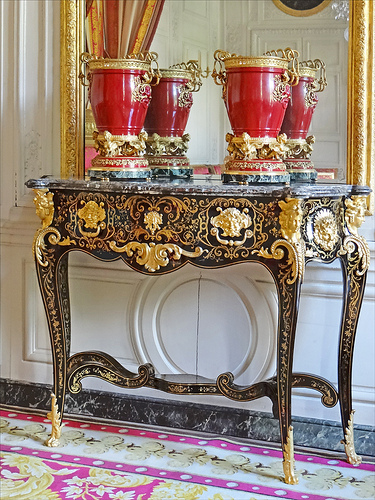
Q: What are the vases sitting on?
A: Table.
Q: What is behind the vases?
A: Mirror.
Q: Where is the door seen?
A: Reflected in the mirror.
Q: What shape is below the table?
A: Round.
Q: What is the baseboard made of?
A: Marble.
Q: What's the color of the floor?
A: White, red and gold.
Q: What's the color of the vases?
A: Red and gold.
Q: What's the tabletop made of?
A: Marble.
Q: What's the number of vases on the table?
A: Two.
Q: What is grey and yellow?
A: Table.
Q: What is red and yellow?
A: Vases.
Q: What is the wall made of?
A: Wood.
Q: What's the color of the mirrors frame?
A: Gold.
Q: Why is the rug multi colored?
A: Designed that way.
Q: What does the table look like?
A: Embroidered black and gold.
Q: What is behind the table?
A: A mirror.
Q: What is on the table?
A: Two red canisters.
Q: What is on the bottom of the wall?
A: A marble border.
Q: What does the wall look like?
A: The wall is white.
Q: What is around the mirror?
A: A gold frame.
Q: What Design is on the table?
A: Gold swir ll s and lion heads.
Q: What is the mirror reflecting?
A: A wall.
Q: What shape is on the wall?
A: A circle.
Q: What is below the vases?
A: A table.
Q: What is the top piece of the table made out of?
A: It's marble.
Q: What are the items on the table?
A: Vases.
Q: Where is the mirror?
A: Hanging on wall.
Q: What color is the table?
A: Black and gold.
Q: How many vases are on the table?
A: 2.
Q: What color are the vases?
A: Red.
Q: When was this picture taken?
A: Daytime.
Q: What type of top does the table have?
A: Marble.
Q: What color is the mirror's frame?
A: Gold.